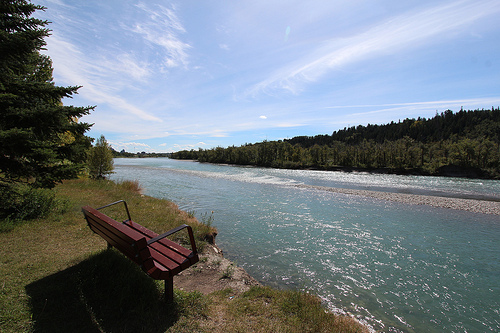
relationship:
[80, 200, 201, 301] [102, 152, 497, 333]
bench beside water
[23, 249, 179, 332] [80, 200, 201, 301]
shadow behind bench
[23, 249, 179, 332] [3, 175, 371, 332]
shadow on ground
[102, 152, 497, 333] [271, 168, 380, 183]
water has ripples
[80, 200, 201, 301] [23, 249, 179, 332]
bench casts shadow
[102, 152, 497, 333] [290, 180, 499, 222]
water has sandbar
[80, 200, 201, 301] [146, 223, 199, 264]
bench has arms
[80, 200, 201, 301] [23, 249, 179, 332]
bench has shadow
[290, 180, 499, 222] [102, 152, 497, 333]
sandbar in water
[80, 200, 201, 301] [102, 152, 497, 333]
bench on side of water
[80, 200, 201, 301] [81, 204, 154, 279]
bench has back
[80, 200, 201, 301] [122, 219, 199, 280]
bench has seat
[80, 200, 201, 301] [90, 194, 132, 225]
bench has rail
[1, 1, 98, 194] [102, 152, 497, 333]
tree on bank of water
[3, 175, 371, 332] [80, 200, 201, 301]
ground beneath bench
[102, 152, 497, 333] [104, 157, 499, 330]
water in river